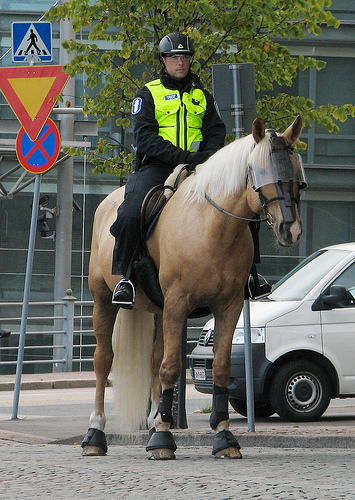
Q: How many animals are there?
A: One.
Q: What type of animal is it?
A: A horse.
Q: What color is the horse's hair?
A: Blonde.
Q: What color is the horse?
A: Tan.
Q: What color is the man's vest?
A: Yellow.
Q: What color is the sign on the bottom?
A: Blue and red.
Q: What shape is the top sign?
A: A square.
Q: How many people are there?
A: One.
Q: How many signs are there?
A: Three.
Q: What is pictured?
A: A policeman riding horseback.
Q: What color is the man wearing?
A: Yellow and black.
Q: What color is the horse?
A: Brown with a blonde mane.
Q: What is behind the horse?
A: A white van.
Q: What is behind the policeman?
A: A tree.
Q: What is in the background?
A: A building.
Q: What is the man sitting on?
A: A horse.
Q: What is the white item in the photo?
A: Van.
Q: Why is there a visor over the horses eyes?
A: For protection.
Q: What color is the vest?
A: Yellow.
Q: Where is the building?
A: In the background.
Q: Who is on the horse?
A: A cop.